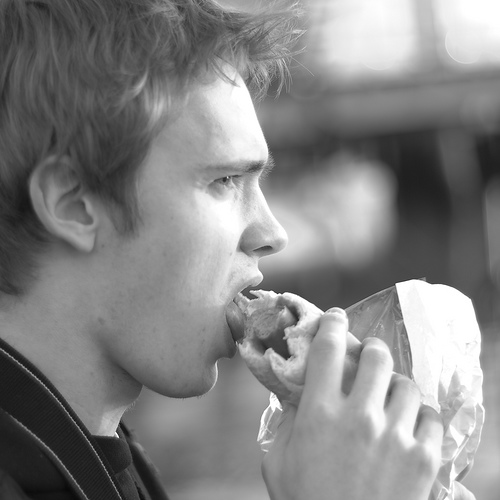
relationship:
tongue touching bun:
[218, 297, 264, 334] [220, 288, 440, 435]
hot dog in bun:
[242, 288, 348, 395] [246, 352, 344, 440]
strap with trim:
[12, 365, 148, 496] [4, 344, 44, 387]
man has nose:
[2, 3, 482, 498] [237, 176, 287, 257]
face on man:
[151, 77, 293, 399] [1, 0, 332, 494]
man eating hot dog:
[2, 3, 482, 498] [242, 288, 384, 413]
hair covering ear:
[1, 70, 139, 205] [23, 148, 100, 255]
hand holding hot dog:
[247, 317, 464, 498] [235, 287, 456, 467]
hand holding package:
[247, 317, 464, 498] [345, 279, 481, 499]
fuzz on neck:
[108, 378, 136, 400] [93, 378, 155, 430]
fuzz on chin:
[108, 378, 136, 400] [155, 380, 215, 405]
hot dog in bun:
[242, 288, 384, 413] [228, 288, 361, 392]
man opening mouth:
[28, 7, 284, 408] [218, 267, 255, 352]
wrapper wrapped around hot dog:
[344, 259, 498, 484] [219, 295, 278, 345]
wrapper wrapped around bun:
[344, 259, 498, 484] [264, 328, 375, 413]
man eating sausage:
[2, 3, 482, 498] [232, 280, 302, 355]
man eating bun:
[2, 3, 482, 498] [268, 280, 381, 398]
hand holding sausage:
[278, 317, 464, 498] [243, 289, 319, 364]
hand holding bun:
[278, 317, 464, 498] [256, 355, 396, 410]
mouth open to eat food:
[221, 267, 259, 351] [229, 277, 396, 418]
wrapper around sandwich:
[344, 259, 498, 484] [232, 281, 404, 425]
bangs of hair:
[180, 6, 347, 109] [1, 12, 309, 273]